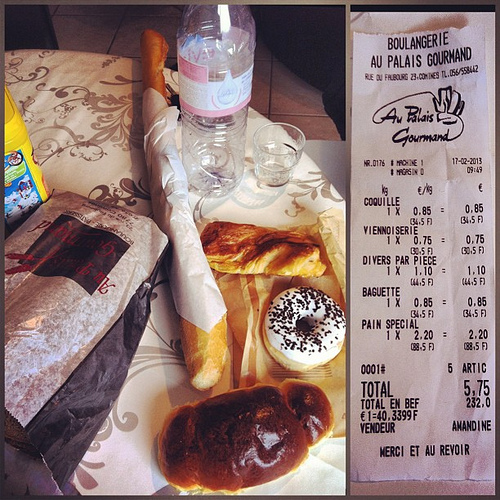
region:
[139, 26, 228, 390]
a baguette wrapped in a white paper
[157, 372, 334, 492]
a brioche on a table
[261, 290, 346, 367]
a doughnut with white glaze and chocolate sprinkles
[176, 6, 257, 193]
a big plastic bottle of water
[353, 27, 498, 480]
a bakery receipt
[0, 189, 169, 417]
a paper bag on a table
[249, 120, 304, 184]
a glass on a table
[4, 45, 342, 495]
a round table with a white and brown tablecloth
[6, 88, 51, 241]
a yellow plastic container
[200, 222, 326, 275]
a pastry on a paper bag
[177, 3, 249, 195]
an empty water bottle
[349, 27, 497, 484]
a receipt for purchased items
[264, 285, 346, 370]
a donut with white icing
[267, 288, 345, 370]
a donut with chocolate sprinkles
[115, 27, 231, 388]
a loaf of bread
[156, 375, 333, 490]
a roll with a dark top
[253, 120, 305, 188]
a glass of water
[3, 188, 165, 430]
a paper bag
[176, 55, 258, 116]
the label on a water bottle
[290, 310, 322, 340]
the center of a donut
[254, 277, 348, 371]
white iced donut with sprinkles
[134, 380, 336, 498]
glossy brown baked bread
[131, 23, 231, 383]
baguette in white paper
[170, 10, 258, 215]
empty plastic bottle on table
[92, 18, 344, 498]
collection of pastries from shop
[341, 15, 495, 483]
receipt for various pastries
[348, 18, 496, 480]
receipt in French language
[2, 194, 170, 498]
empty bag on table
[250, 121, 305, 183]
empty water glass on table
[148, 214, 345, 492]
various pastries sitting on paper